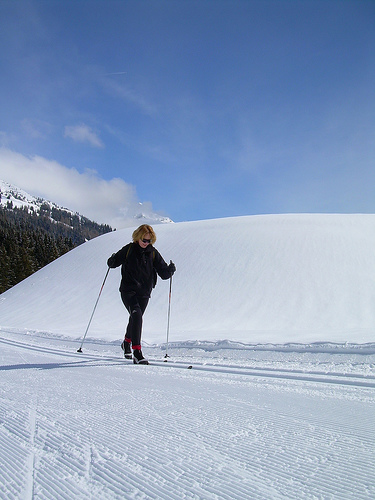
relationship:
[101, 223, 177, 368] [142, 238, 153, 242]
woman wearing sunglasses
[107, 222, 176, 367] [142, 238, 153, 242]
woman wearing sunglasses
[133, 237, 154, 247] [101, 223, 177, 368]
sunglasses on woman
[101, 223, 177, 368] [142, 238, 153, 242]
woman on sunglasses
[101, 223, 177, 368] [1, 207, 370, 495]
woman skiing in snow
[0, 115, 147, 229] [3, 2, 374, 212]
clouds in sky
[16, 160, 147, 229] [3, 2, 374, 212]
clouds in sky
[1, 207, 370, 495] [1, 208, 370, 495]
snow on ground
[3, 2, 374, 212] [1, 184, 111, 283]
sky over mountain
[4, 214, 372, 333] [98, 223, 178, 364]
mound behind skier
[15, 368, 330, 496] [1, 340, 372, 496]
narrow ridges on ski path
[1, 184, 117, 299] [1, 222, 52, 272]
mountain covered with trees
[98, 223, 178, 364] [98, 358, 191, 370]
skier looking down at skis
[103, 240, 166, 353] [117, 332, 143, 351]
outfit has cuff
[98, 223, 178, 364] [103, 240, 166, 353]
skier wearing outfit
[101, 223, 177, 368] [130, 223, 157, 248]
woman has hair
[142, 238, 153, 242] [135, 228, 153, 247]
sunglasses on face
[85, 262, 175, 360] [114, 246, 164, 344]
ski pole on side of body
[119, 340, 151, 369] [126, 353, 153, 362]
ski boots with trim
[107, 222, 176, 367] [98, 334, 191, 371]
woman on skis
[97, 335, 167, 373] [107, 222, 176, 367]
shoes on woman